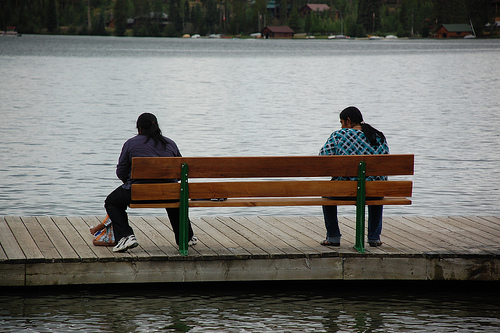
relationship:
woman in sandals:
[320, 106, 390, 248] [321, 236, 383, 247]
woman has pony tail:
[320, 106, 390, 248] [360, 115, 387, 147]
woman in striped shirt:
[320, 106, 390, 248] [316, 125, 391, 181]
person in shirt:
[98, 114, 205, 251] [115, 134, 182, 189]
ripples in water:
[134, 301, 412, 332] [7, 30, 484, 205]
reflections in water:
[137, 296, 405, 331] [7, 30, 484, 205]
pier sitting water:
[3, 212, 498, 280] [1, 283, 498, 330]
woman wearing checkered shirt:
[320, 106, 390, 248] [316, 128, 389, 181]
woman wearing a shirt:
[103, 113, 198, 253] [116, 131, 187, 188]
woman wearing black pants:
[103, 113, 198, 253] [101, 181, 195, 244]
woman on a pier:
[320, 106, 390, 248] [3, 212, 498, 280]